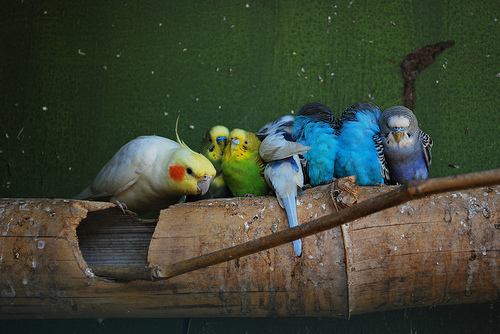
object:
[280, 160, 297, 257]
feathers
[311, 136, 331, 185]
feathers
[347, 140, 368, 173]
feathers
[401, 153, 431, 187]
feathers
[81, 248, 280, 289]
twig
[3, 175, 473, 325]
wood log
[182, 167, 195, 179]
eye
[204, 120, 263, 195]
lovebirds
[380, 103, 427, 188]
bird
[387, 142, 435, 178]
body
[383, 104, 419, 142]
head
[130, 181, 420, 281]
crack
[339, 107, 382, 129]
head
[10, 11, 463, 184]
fabric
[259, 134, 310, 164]
wing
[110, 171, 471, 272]
stick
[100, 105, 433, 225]
together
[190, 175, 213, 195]
beak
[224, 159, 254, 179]
chest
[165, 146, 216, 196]
head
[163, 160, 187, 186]
cheek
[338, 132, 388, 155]
wings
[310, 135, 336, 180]
wings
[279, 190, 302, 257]
bird tail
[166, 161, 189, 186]
spot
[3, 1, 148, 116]
wall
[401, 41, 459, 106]
spot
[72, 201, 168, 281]
hole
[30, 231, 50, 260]
spot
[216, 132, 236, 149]
spot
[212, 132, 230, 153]
beak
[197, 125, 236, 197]
bird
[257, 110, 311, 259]
bird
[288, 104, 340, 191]
bird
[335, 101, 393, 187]
bird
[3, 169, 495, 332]
trunk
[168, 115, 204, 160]
hair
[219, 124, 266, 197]
bird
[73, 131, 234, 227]
bird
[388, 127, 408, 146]
beak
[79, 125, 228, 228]
bird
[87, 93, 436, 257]
birds